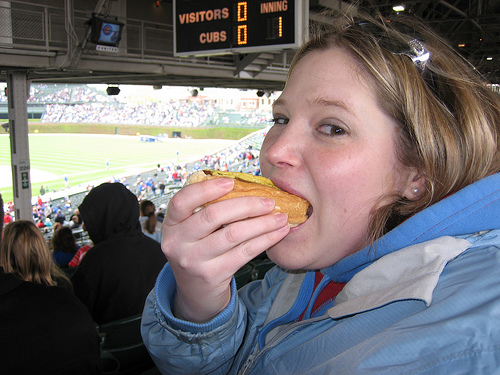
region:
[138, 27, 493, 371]
A woman eating a hot dog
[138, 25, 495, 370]
A woman at a baseball game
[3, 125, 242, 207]
A baseball diamond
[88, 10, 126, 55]
A small television with sports scores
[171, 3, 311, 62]
A baseball scoreboard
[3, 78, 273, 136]
Baseball spectators across the baseball diamond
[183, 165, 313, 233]
A baseball stadium hotdog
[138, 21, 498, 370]
A woman in a light blue jacket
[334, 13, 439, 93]
A pair of glasses in a woman's hair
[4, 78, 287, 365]
Spectators at a baseball game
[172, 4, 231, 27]
The word visitors lit up on a sign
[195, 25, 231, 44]
The word cubs lit up on a sign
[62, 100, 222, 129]
A blur of spectators in the background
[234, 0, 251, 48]
The number 00 on the scoreboard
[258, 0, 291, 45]
The word innings and the number 1 lit on the sign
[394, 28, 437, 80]
A silver barrette on someone's head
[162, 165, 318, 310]
A hand holding onto a hotdog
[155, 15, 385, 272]
A person eating a hot dog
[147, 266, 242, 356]
The sleeve of a blue jacket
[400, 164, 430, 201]
An earlobe with a white earring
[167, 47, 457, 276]
Woman eating a hotdog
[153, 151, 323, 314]
The woman is holding a hotdog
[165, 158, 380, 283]
Woman is biting a hotdog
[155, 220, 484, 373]
The woman is wearing a blue jacket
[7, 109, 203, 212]
A baseball game in the distance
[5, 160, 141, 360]
Spectators watch the baseball game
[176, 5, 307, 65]
Scoreboard displays the score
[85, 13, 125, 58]
Television on the wall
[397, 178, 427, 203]
Ear ring on the woman's left ear lobe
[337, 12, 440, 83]
A pair of glasses on the woman's head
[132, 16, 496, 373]
young woman eating a hotdog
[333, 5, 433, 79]
pair of glasses on a woman's head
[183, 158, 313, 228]
hotdog bun with a hotdog and mustard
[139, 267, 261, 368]
blue female jacket and sleeve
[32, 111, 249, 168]
part of a sports field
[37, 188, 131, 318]
spectators watching sports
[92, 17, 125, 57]
small black television monitor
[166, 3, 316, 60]
baseball score screen showing zeros for both teams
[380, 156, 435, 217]
woman's pearl earring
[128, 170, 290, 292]
woman's hand holding a hotdog